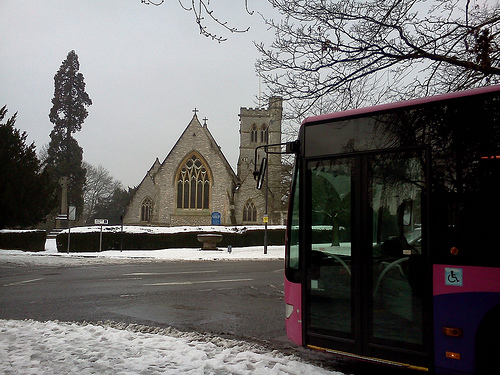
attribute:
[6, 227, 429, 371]
snow — white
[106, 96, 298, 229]
church — stone, tan, brown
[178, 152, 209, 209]
window — classic, gothic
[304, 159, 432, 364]
door — closed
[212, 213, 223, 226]
door — blue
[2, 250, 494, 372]
road — wet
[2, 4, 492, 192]
sky — gray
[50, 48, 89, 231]
tree — conifer, tall, pine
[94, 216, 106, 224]
sign — white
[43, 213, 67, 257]
steps —  church's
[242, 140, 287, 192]
mirror — clear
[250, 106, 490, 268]
bus — pink and black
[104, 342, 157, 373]
snow — in stack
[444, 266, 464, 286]
symbol —  White,  wheelchair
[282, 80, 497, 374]
bus — waiting, black, pink, blue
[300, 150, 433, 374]
doors — to enter bus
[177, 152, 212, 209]
window — large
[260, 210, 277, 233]
sign —  Yellow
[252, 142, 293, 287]
pole —   dark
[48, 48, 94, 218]
tree — tall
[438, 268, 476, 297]
sign —  bus',  equipped for disabled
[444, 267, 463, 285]
symbol — handicap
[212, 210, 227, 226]
sign — blue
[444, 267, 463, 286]
sign —  for HANDICAPPED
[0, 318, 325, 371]
snow — white